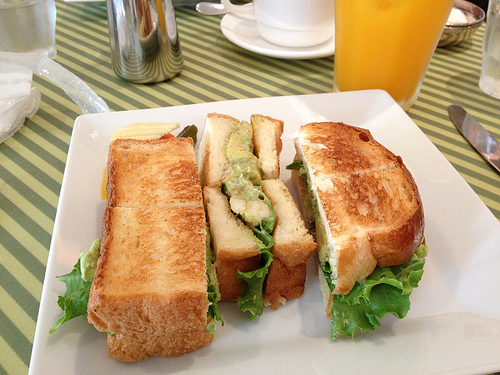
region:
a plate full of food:
[65, 95, 465, 357]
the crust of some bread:
[117, 312, 184, 367]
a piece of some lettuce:
[38, 268, 89, 326]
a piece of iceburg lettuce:
[74, 233, 101, 275]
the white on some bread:
[217, 211, 241, 242]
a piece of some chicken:
[224, 176, 264, 216]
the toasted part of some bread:
[332, 165, 393, 235]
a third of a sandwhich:
[185, 105, 319, 292]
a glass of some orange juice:
[322, 6, 444, 108]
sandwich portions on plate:
[40, 87, 439, 347]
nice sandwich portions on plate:
[64, 105, 447, 358]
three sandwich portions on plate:
[63, 82, 458, 349]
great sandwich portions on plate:
[63, 97, 456, 350]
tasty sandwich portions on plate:
[57, 87, 454, 357]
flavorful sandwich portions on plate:
[47, 89, 460, 359]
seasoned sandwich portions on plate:
[62, 93, 462, 360]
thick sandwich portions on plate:
[49, 90, 445, 357]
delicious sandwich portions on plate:
[61, 86, 449, 356]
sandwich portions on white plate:
[47, 83, 453, 365]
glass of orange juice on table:
[325, 0, 458, 119]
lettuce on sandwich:
[287, 155, 443, 343]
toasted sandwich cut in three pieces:
[45, 102, 440, 372]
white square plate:
[22, 83, 498, 374]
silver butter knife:
[436, 97, 498, 177]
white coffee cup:
[217, 0, 334, 55]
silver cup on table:
[99, 0, 204, 89]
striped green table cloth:
[1, 1, 498, 373]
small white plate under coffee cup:
[213, 1, 336, 63]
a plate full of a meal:
[30, 86, 471, 373]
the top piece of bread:
[102, 146, 207, 327]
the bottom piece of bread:
[92, 318, 216, 359]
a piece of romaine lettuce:
[43, 268, 93, 314]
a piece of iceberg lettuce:
[66, 240, 101, 261]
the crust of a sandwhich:
[125, 295, 198, 365]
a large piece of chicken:
[221, 175, 282, 228]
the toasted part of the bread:
[326, 170, 382, 211]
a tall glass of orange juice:
[330, 9, 438, 113]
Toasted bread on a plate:
[132, 154, 178, 284]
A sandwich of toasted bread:
[128, 302, 182, 349]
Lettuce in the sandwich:
[244, 275, 259, 310]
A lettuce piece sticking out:
[357, 286, 403, 310]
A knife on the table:
[467, 122, 478, 137]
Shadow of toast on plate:
[156, 360, 175, 370]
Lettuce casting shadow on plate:
[381, 327, 392, 336]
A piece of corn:
[128, 126, 160, 136]